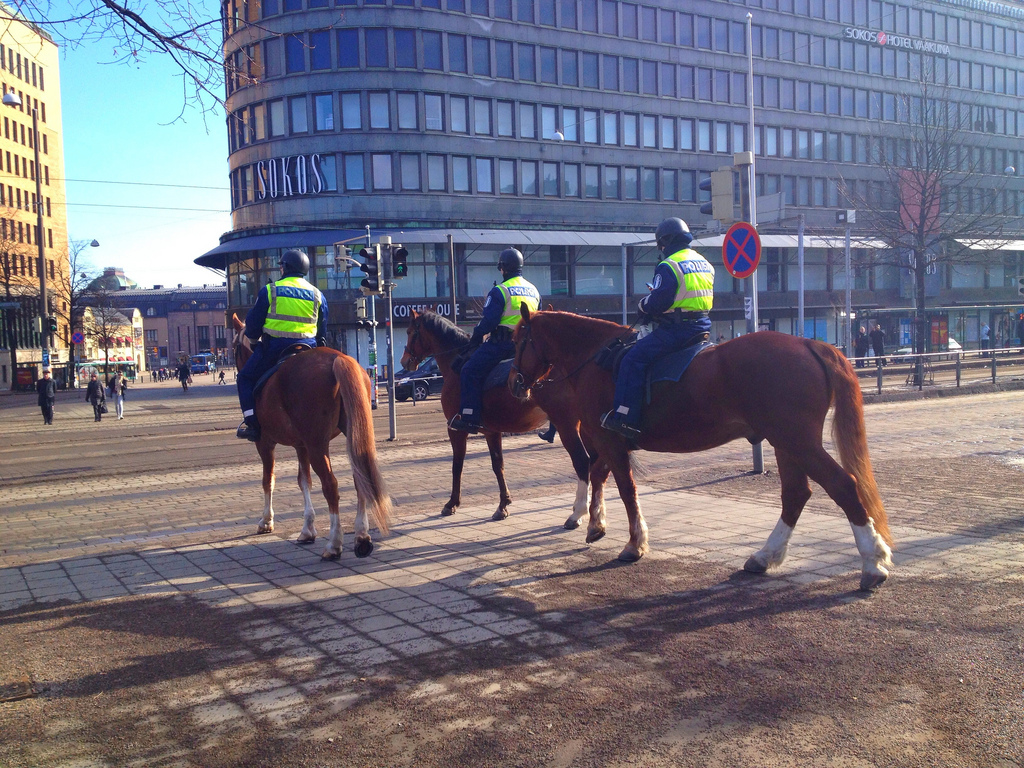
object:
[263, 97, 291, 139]
window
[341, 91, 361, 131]
window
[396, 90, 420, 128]
window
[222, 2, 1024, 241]
brown building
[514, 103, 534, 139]
window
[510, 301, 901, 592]
brown horse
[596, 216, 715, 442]
enforcement officer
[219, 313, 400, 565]
brown horse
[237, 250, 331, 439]
enforcement officer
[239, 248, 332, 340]
vest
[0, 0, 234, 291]
sky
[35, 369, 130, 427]
people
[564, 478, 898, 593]
white hooves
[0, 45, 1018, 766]
outdoors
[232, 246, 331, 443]
police officer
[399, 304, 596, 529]
brown horse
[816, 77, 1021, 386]
tree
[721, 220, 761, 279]
sign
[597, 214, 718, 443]
officer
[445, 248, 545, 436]
officer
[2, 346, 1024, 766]
street